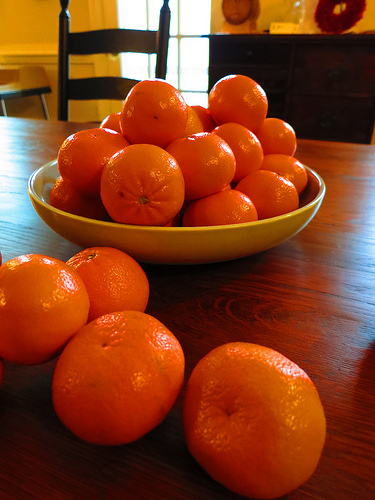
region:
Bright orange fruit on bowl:
[99, 148, 171, 213]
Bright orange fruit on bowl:
[118, 74, 191, 142]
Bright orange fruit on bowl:
[205, 71, 263, 136]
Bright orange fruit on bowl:
[215, 120, 274, 178]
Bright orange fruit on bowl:
[165, 129, 240, 197]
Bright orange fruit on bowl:
[58, 119, 117, 195]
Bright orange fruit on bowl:
[21, 64, 346, 281]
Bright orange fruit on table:
[192, 326, 330, 494]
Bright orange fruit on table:
[27, 286, 201, 453]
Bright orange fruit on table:
[5, 237, 88, 370]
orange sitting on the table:
[186, 328, 359, 492]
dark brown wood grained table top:
[260, 276, 354, 344]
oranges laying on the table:
[4, 236, 316, 494]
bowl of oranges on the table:
[44, 58, 338, 281]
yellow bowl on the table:
[186, 217, 326, 266]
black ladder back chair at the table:
[52, 2, 185, 139]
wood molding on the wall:
[13, 39, 56, 69]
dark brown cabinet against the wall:
[267, 30, 369, 123]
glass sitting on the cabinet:
[289, 0, 316, 42]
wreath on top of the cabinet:
[312, 2, 370, 42]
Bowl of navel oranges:
[7, 68, 368, 269]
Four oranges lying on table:
[6, 234, 334, 495]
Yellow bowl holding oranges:
[23, 124, 335, 256]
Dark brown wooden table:
[7, 248, 370, 489]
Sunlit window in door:
[110, 3, 208, 84]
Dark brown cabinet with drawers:
[203, 23, 374, 139]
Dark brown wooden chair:
[47, 10, 173, 120]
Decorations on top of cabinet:
[207, 3, 374, 37]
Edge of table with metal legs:
[0, 61, 55, 116]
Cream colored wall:
[2, 1, 117, 118]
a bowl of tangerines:
[29, 71, 328, 245]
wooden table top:
[0, 117, 372, 499]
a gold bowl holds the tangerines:
[26, 154, 329, 256]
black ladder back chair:
[35, 5, 177, 127]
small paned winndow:
[121, 1, 207, 115]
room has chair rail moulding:
[0, 31, 93, 90]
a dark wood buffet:
[204, 33, 373, 144]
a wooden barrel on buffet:
[218, 0, 262, 40]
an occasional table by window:
[0, 66, 55, 124]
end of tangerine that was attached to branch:
[123, 174, 163, 222]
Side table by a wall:
[0, 60, 49, 120]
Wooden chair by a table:
[58, 0, 169, 121]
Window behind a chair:
[114, 1, 210, 117]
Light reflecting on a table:
[1, 116, 36, 232]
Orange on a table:
[186, 341, 326, 497]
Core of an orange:
[137, 194, 149, 204]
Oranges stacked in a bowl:
[30, 75, 325, 265]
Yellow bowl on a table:
[26, 167, 326, 265]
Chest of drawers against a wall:
[202, 29, 373, 152]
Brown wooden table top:
[1, 116, 371, 499]